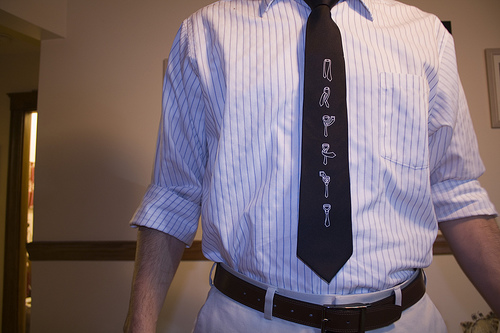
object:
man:
[122, 0, 499, 333]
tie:
[295, 0, 353, 283]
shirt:
[129, 0, 500, 296]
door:
[2, 90, 38, 333]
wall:
[38, 0, 499, 333]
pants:
[194, 262, 447, 333]